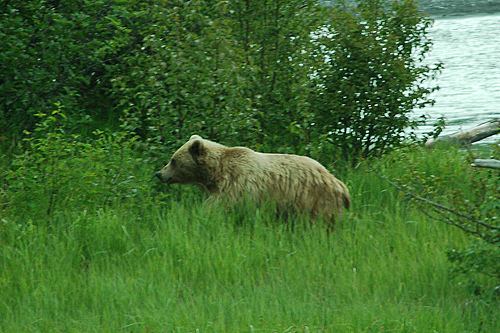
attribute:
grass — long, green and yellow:
[1, 192, 489, 331]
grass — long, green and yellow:
[58, 230, 376, 331]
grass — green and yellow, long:
[93, 191, 428, 331]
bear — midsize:
[148, 126, 359, 238]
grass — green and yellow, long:
[6, 125, 499, 329]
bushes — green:
[293, 17, 397, 129]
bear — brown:
[148, 129, 364, 230]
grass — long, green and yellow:
[180, 252, 240, 332]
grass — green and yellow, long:
[44, 188, 206, 293]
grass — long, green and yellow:
[88, 201, 420, 303]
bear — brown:
[156, 130, 355, 232]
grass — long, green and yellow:
[106, 227, 430, 317]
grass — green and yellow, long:
[178, 213, 219, 286]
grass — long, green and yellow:
[240, 214, 409, 320]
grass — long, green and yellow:
[312, 255, 417, 297]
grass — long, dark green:
[329, 239, 428, 301]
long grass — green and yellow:
[90, 225, 314, 331]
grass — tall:
[104, 212, 352, 311]